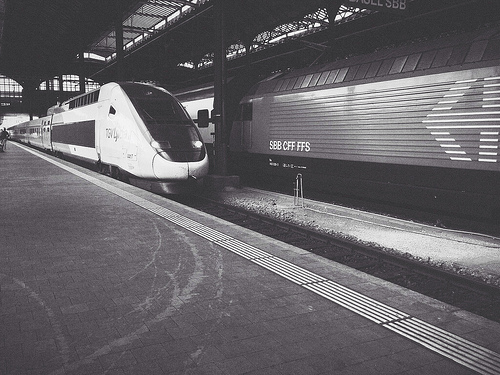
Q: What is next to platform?
A: Train.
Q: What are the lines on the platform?
A: Safety lines.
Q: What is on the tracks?
A: Train.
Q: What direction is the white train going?
A: Right.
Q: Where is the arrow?
A: On train.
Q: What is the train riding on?
A: Tracks.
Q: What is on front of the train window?
A: Windshield wipers.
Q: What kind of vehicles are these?
A: Commuter trains.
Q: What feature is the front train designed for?
A: Speed.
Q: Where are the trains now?
A: Inside of a station.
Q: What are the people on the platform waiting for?
A: To board the train.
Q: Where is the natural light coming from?
A: Overhead skylights.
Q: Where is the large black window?
A: On the front of the left train.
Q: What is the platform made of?
A: Brick pavers.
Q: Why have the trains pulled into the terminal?
A: To load and unload passengers.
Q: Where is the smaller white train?
A: On the left.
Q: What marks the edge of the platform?
A: Painted lines.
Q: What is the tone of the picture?
A: Black and White.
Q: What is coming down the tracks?
A: Train.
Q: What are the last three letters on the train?
A: FFS.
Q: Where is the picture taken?
A: Subway.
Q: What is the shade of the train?
A: White.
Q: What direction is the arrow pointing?
A: Left.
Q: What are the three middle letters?
A: CFF.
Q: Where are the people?
A: On the left.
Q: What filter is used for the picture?
A: Black and white.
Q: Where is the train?
A: In the station.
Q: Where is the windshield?
A: On the front of the train.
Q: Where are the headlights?
A: Next to the windshield.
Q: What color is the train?
A: White.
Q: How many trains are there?
A: Two.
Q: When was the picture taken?
A: Midday.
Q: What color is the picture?
A: Black and white.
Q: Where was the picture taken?
A: The train station.